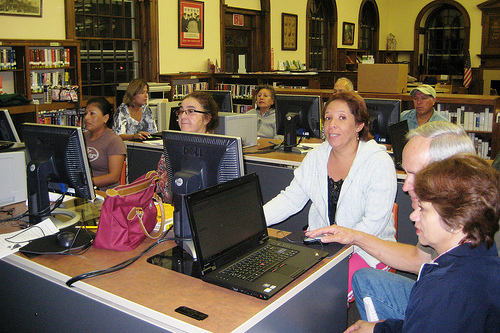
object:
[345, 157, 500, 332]
woman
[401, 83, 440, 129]
man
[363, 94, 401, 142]
computer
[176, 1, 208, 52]
picture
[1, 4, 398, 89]
wall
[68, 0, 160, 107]
window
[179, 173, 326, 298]
laptop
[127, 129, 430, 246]
table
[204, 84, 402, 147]
computers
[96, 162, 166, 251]
bag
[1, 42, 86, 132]
bookcase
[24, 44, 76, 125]
books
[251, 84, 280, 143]
lady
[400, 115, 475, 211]
man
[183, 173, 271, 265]
screen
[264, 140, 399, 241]
jacket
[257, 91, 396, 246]
woman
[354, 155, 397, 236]
white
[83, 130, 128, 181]
shirt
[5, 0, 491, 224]
library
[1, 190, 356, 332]
near table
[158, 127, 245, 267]
computer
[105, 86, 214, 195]
lady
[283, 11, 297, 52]
poster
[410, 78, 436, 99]
cap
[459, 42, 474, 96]
flag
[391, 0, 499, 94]
back wall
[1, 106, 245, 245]
computers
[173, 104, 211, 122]
glasses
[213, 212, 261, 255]
black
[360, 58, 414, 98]
box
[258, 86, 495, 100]
counter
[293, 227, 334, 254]
mouse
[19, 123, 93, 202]
back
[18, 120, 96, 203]
monitor